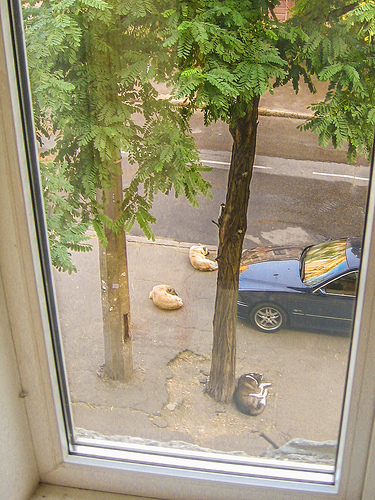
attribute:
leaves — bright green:
[40, 13, 207, 235]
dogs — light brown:
[136, 238, 219, 313]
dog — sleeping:
[186, 243, 225, 277]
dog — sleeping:
[144, 281, 190, 314]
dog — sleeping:
[228, 369, 273, 420]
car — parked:
[234, 232, 363, 341]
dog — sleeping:
[168, 237, 238, 289]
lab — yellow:
[145, 281, 186, 316]